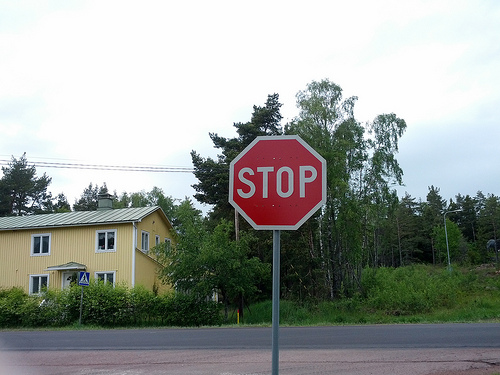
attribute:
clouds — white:
[97, 45, 392, 183]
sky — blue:
[388, 45, 494, 220]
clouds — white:
[2, 1, 157, 64]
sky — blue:
[430, 147, 498, 187]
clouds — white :
[1, 1, 496, 211]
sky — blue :
[2, 1, 497, 208]